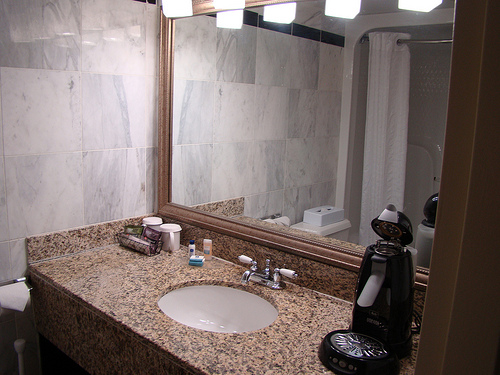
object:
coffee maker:
[317, 202, 418, 374]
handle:
[271, 268, 300, 287]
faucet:
[235, 253, 299, 293]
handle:
[235, 254, 260, 275]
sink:
[152, 278, 280, 336]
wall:
[2, 0, 155, 218]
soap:
[188, 253, 206, 267]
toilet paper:
[1, 283, 32, 312]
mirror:
[173, 0, 457, 271]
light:
[212, 9, 244, 31]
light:
[261, 5, 296, 27]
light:
[325, 0, 363, 20]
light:
[399, 0, 442, 14]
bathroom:
[1, 0, 499, 373]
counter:
[24, 217, 422, 374]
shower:
[354, 26, 446, 262]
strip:
[243, 11, 349, 46]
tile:
[85, 74, 145, 151]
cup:
[159, 223, 184, 251]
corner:
[157, 230, 163, 244]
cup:
[143, 217, 163, 230]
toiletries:
[203, 238, 212, 260]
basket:
[116, 225, 164, 257]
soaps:
[143, 227, 161, 243]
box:
[303, 205, 345, 228]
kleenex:
[319, 208, 329, 213]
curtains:
[356, 33, 410, 247]